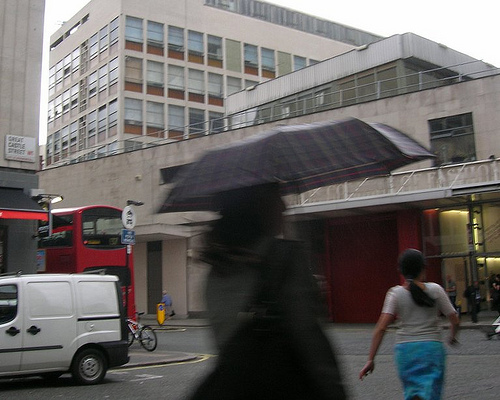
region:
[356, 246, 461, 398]
A girl running in the street.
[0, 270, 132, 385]
A van in the street.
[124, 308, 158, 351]
A bike in the street.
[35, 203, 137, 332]
Part of a bus.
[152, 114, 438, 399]
A lady holding an umbrella.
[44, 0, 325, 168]
Windows on a building.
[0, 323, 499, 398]
An asphalt paved road.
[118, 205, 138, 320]
A sign on a pole.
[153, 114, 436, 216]
An opened black umbrella.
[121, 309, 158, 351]
A bike on a sidewalk.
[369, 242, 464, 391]
this is a lady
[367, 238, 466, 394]
the lady is walking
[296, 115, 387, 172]
this is an umbrella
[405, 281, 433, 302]
this is the hair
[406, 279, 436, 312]
the long is long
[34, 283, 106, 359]
this is the car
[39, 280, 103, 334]
the car is white in collor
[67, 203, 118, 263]
this is a twin bus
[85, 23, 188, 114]
this is a building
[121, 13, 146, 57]
The window is rectangular.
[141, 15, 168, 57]
The window is rectangular.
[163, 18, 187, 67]
The window is rectangular.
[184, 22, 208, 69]
The window is rectangular.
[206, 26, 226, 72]
The window is rectangular.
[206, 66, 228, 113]
The window is rectangular.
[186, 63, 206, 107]
The window is rectangular.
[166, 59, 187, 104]
The window is rectangular.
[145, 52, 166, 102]
The window is rectangular.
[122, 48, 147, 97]
The window is rectangular.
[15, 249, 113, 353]
A car is at a park stop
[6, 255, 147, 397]
the car is white in color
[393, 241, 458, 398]
a ladyis crossing th road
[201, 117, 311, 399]
a laady is covered with an umbreellla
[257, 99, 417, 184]
the umbrella is black in color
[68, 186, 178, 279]
bus is on thhe highway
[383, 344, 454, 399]
the skirt is blue in color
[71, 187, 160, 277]
the car is red in color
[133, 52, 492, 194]
buildings are beside the road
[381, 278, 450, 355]
the blouse is gray in color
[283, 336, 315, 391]
art of a hand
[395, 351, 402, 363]
part of a skirt